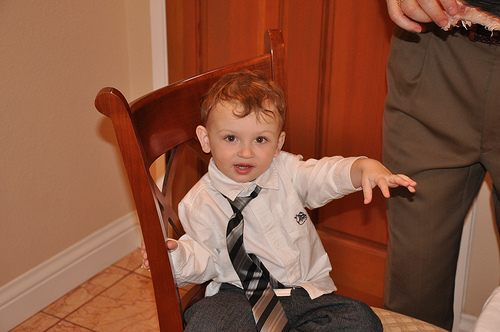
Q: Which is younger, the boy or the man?
A: The boy is younger than the man.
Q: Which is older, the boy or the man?
A: The man is older than the boy.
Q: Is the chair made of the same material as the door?
A: Yes, both the chair and the door are made of wood.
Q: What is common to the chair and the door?
A: The material, both the chair and the door are wooden.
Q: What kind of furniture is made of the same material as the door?
A: The chair is made of the same material as the door.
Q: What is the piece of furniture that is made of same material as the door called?
A: The piece of furniture is a chair.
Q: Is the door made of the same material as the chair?
A: Yes, both the door and the chair are made of wood.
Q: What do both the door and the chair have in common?
A: The material, both the door and the chair are wooden.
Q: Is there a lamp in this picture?
A: No, there are no lamps.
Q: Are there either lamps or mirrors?
A: No, there are no lamps or mirrors.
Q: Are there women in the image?
A: No, there are no women.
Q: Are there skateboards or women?
A: No, there are no women or skateboards.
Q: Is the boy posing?
A: Yes, the boy is posing.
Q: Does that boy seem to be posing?
A: Yes, the boy is posing.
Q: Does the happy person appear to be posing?
A: Yes, the boy is posing.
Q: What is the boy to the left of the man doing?
A: The boy is posing.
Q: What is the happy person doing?
A: The boy is posing.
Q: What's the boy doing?
A: The boy is posing.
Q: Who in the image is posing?
A: The boy is posing.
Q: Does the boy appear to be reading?
A: No, the boy is posing.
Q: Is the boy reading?
A: No, the boy is posing.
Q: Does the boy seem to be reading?
A: No, the boy is posing.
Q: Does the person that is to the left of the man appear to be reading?
A: No, the boy is posing.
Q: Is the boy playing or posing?
A: The boy is posing.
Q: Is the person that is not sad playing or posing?
A: The boy is posing.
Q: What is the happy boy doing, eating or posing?
A: The boy is posing.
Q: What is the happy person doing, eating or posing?
A: The boy is posing.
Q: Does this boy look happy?
A: Yes, the boy is happy.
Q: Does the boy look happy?
A: Yes, the boy is happy.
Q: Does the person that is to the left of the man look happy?
A: Yes, the boy is happy.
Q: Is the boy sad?
A: No, the boy is happy.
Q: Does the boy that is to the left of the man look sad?
A: No, the boy is happy.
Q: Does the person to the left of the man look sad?
A: No, the boy is happy.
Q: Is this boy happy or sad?
A: The boy is happy.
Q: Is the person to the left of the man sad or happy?
A: The boy is happy.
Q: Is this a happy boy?
A: Yes, this is a happy boy.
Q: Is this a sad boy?
A: No, this is a happy boy.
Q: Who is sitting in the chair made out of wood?
A: The boy is sitting in the chair.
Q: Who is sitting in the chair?
A: The boy is sitting in the chair.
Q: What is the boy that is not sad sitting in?
A: The boy is sitting in the chair.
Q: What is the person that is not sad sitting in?
A: The boy is sitting in the chair.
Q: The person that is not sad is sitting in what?
A: The boy is sitting in the chair.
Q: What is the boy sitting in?
A: The boy is sitting in the chair.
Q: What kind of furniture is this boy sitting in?
A: The boy is sitting in the chair.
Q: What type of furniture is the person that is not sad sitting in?
A: The boy is sitting in the chair.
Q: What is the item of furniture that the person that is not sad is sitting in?
A: The piece of furniture is a chair.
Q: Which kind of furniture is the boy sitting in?
A: The boy is sitting in the chair.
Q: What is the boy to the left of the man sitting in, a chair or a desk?
A: The boy is sitting in a chair.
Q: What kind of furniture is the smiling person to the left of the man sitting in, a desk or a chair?
A: The boy is sitting in a chair.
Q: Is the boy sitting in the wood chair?
A: Yes, the boy is sitting in the chair.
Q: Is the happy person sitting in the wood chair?
A: Yes, the boy is sitting in the chair.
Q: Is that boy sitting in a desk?
A: No, the boy is sitting in the chair.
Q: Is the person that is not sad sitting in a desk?
A: No, the boy is sitting in the chair.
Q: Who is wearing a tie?
A: The boy is wearing a tie.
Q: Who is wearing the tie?
A: The boy is wearing a tie.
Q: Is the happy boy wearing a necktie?
A: Yes, the boy is wearing a necktie.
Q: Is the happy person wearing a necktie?
A: Yes, the boy is wearing a necktie.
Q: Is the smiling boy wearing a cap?
A: No, the boy is wearing a necktie.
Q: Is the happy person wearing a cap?
A: No, the boy is wearing a necktie.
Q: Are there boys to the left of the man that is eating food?
A: Yes, there is a boy to the left of the man.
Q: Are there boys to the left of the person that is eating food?
A: Yes, there is a boy to the left of the man.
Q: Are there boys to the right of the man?
A: No, the boy is to the left of the man.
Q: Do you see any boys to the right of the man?
A: No, the boy is to the left of the man.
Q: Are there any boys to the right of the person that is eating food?
A: No, the boy is to the left of the man.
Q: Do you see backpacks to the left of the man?
A: No, there is a boy to the left of the man.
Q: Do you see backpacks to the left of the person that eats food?
A: No, there is a boy to the left of the man.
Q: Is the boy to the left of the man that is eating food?
A: Yes, the boy is to the left of the man.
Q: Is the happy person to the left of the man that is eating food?
A: Yes, the boy is to the left of the man.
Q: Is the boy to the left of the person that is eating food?
A: Yes, the boy is to the left of the man.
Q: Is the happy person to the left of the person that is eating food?
A: Yes, the boy is to the left of the man.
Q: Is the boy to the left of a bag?
A: No, the boy is to the left of the man.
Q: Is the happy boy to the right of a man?
A: No, the boy is to the left of a man.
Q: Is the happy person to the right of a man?
A: No, the boy is to the left of a man.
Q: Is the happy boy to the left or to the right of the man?
A: The boy is to the left of the man.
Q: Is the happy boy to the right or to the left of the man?
A: The boy is to the left of the man.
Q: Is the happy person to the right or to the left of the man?
A: The boy is to the left of the man.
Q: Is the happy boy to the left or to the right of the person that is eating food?
A: The boy is to the left of the man.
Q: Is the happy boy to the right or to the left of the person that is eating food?
A: The boy is to the left of the man.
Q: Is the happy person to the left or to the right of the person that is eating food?
A: The boy is to the left of the man.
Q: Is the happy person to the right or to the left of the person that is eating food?
A: The boy is to the left of the man.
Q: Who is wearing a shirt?
A: The boy is wearing a shirt.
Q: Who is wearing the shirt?
A: The boy is wearing a shirt.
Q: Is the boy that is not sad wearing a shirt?
A: Yes, the boy is wearing a shirt.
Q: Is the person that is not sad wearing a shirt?
A: Yes, the boy is wearing a shirt.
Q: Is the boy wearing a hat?
A: No, the boy is wearing a shirt.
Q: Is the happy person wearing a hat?
A: No, the boy is wearing a shirt.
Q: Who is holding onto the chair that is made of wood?
A: The boy is holding onto the chair.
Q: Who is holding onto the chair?
A: The boy is holding onto the chair.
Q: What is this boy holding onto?
A: The boy is holding onto the chair.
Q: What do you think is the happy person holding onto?
A: The boy is holding onto the chair.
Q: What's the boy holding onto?
A: The boy is holding onto the chair.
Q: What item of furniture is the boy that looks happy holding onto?
A: The boy is holding onto the chair.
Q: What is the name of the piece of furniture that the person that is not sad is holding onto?
A: The piece of furniture is a chair.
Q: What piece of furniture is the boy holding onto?
A: The boy is holding onto the chair.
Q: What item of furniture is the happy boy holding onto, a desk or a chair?
A: The boy is holding onto a chair.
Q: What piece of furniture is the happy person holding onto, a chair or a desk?
A: The boy is holding onto a chair.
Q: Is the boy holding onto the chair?
A: Yes, the boy is holding onto the chair.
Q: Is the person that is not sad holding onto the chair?
A: Yes, the boy is holding onto the chair.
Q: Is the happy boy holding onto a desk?
A: No, the boy is holding onto the chair.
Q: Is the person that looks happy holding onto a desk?
A: No, the boy is holding onto the chair.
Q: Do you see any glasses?
A: No, there are no glasses.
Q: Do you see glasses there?
A: No, there are no glasses.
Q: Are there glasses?
A: No, there are no glasses.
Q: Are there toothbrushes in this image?
A: No, there are no toothbrushes.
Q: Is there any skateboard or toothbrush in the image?
A: No, there are no toothbrushes or skateboards.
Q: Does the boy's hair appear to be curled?
A: Yes, the hair is curled.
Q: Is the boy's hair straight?
A: No, the hair is curled.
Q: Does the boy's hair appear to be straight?
A: No, the hair is curled.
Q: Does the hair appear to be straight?
A: No, the hair is curled.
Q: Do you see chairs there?
A: Yes, there is a chair.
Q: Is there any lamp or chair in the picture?
A: Yes, there is a chair.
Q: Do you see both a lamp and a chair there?
A: No, there is a chair but no lamps.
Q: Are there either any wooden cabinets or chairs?
A: Yes, there is a wood chair.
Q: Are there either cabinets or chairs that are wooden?
A: Yes, the chair is wooden.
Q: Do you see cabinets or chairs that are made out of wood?
A: Yes, the chair is made of wood.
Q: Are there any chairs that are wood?
A: Yes, there is a wood chair.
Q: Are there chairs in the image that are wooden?
A: Yes, there is a chair that is wooden.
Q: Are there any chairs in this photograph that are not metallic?
A: Yes, there is a wooden chair.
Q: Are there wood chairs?
A: Yes, there is a chair that is made of wood.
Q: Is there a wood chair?
A: Yes, there is a chair that is made of wood.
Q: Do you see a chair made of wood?
A: Yes, there is a chair that is made of wood.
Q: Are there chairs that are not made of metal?
A: Yes, there is a chair that is made of wood.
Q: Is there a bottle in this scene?
A: No, there are no bottles.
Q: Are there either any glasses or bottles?
A: No, there are no bottles or glasses.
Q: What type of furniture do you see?
A: The furniture is a chair.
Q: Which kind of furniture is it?
A: The piece of furniture is a chair.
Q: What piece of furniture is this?
A: This is a chair.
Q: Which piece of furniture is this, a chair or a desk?
A: This is a chair.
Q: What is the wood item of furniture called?
A: The piece of furniture is a chair.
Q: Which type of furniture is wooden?
A: The furniture is a chair.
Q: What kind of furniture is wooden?
A: The furniture is a chair.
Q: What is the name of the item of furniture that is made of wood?
A: The piece of furniture is a chair.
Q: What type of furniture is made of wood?
A: The furniture is a chair.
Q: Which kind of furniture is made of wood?
A: The furniture is a chair.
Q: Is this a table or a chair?
A: This is a chair.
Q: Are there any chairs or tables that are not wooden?
A: No, there is a chair but it is wooden.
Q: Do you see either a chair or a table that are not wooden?
A: No, there is a chair but it is wooden.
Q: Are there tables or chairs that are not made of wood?
A: No, there is a chair but it is made of wood.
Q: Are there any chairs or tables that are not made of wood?
A: No, there is a chair but it is made of wood.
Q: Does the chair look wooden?
A: Yes, the chair is wooden.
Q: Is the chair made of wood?
A: Yes, the chair is made of wood.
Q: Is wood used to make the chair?
A: Yes, the chair is made of wood.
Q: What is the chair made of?
A: The chair is made of wood.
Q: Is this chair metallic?
A: No, the chair is wooden.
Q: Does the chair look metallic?
A: No, the chair is wooden.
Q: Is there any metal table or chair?
A: No, there is a chair but it is wooden.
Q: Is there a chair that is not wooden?
A: No, there is a chair but it is wooden.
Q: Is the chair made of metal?
A: No, the chair is made of wood.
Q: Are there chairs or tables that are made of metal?
A: No, there is a chair but it is made of wood.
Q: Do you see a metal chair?
A: No, there is a chair but it is made of wood.